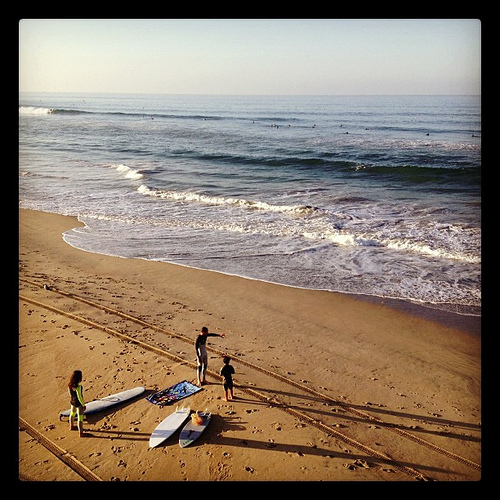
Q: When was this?
A: Daytime.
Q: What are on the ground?
A: Surfboards.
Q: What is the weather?
A: Sunny.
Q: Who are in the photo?
A: People.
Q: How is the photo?
A: Clear.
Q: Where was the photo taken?
A: Beach.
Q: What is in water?
A: Waves.